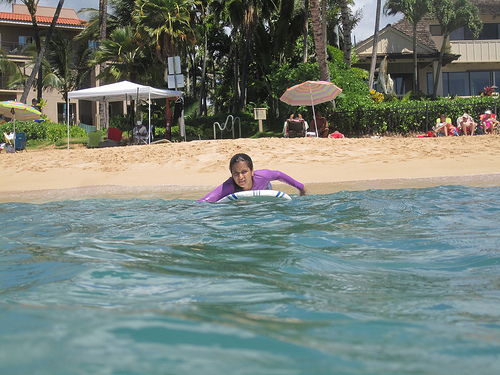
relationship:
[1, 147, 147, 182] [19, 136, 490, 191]
sand on beach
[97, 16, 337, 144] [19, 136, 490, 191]
palms behind beach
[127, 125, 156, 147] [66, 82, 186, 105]
man under awning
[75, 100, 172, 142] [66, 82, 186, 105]
posts with awning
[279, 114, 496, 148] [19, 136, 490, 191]
people on beach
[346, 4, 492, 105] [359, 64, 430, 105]
house has entrance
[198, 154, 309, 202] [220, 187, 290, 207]
woman on board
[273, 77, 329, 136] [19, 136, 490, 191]
umbrella on beach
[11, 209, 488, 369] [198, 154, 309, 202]
water around woman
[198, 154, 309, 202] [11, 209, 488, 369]
woman in water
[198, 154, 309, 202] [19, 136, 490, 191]
woman on beach